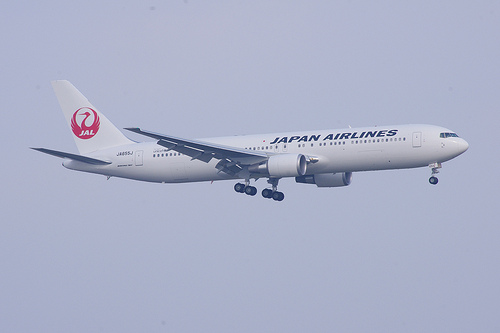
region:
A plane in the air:
[26, 75, 472, 202]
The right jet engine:
[245, 150, 320, 178]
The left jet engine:
[308, 168, 351, 188]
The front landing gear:
[428, 164, 442, 185]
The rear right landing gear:
[231, 177, 258, 198]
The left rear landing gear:
[260, 178, 285, 203]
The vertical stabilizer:
[50, 74, 123, 149]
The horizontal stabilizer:
[30, 140, 110, 167]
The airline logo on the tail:
[70, 105, 101, 139]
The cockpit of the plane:
[437, 123, 470, 160]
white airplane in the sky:
[39, 71, 474, 207]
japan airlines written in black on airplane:
[268, 125, 403, 143]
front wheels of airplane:
[423, 175, 440, 187]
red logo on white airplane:
[66, 103, 99, 141]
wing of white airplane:
[125, 118, 260, 178]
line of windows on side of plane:
[144, 131, 416, 163]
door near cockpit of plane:
[410, 128, 423, 151]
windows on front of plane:
[435, 130, 461, 142]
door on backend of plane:
[131, 147, 145, 167]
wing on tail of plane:
[30, 135, 101, 167]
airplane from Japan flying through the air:
[35, 78, 468, 202]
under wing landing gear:
[233, 178, 284, 205]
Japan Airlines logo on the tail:
[70, 106, 98, 141]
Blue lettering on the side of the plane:
[270, 128, 396, 144]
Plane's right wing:
[127, 124, 317, 181]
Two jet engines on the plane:
[268, 154, 351, 185]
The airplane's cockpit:
[436, 128, 456, 138]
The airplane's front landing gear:
[426, 164, 441, 183]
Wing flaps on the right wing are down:
[157, 140, 241, 177]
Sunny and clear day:
[8, 7, 498, 318]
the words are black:
[270, 127, 410, 144]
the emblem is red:
[68, 100, 105, 141]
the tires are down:
[263, 184, 292, 205]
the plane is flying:
[35, 73, 480, 207]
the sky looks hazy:
[187, 264, 282, 296]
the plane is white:
[210, 120, 441, 175]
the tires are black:
[230, 178, 259, 201]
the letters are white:
[72, 126, 103, 144]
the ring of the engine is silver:
[295, 149, 309, 183]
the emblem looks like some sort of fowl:
[68, 102, 103, 144]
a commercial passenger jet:
[30, 78, 466, 200]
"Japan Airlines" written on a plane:
[268, 129, 399, 144]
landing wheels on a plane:
[233, 175, 258, 195]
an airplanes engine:
[249, 152, 307, 181]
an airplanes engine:
[295, 170, 355, 190]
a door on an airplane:
[410, 133, 418, 149]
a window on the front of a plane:
[440, 132, 457, 139]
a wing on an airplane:
[121, 123, 270, 169]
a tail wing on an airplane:
[49, 78, 129, 148]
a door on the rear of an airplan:
[135, 149, 144, 169]